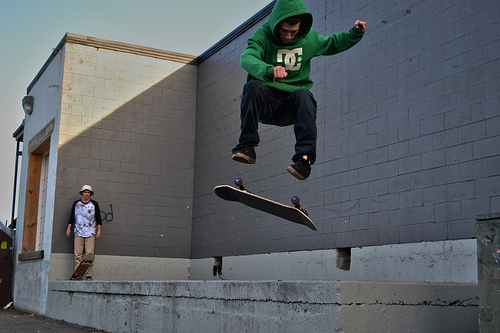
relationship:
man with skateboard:
[63, 183, 106, 287] [64, 251, 96, 283]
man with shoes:
[230, 2, 371, 181] [281, 153, 314, 183]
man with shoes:
[230, 2, 371, 181] [230, 142, 263, 169]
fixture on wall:
[18, 94, 37, 117] [7, 38, 68, 317]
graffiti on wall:
[84, 199, 119, 225] [43, 37, 202, 321]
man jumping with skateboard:
[63, 183, 106, 287] [210, 175, 321, 233]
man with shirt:
[63, 183, 106, 287] [65, 196, 104, 241]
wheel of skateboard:
[232, 175, 245, 185] [210, 175, 321, 233]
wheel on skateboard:
[288, 194, 301, 209] [210, 175, 321, 233]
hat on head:
[75, 183, 97, 195] [79, 183, 95, 201]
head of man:
[79, 183, 95, 201] [63, 183, 106, 287]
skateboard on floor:
[210, 175, 321, 233] [51, 274, 476, 310]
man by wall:
[63, 183, 106, 287] [43, 37, 202, 321]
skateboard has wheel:
[210, 175, 321, 233] [232, 175, 245, 185]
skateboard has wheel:
[210, 175, 321, 233] [288, 194, 301, 209]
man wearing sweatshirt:
[230, 2, 371, 181] [235, 1, 368, 99]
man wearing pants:
[230, 2, 371, 181] [232, 77, 323, 168]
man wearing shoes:
[63, 183, 106, 287] [281, 153, 314, 183]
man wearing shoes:
[230, 2, 371, 181] [230, 142, 263, 169]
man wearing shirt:
[63, 183, 106, 287] [65, 196, 104, 241]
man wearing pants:
[63, 183, 106, 287] [69, 232, 94, 281]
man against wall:
[63, 183, 106, 287] [43, 37, 202, 321]